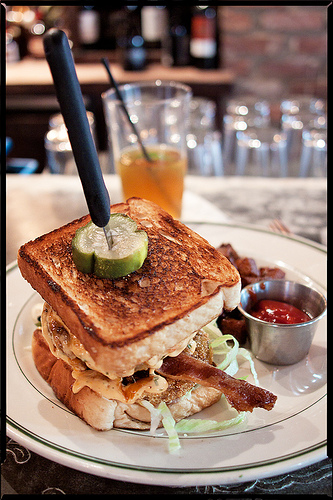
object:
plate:
[6, 217, 327, 487]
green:
[92, 255, 127, 280]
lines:
[7, 217, 330, 485]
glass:
[101, 80, 193, 223]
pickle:
[71, 213, 149, 280]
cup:
[236, 279, 328, 368]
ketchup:
[250, 295, 310, 324]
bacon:
[154, 352, 278, 412]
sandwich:
[17, 196, 279, 452]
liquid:
[115, 145, 187, 222]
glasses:
[45, 92, 327, 177]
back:
[0, 1, 327, 179]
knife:
[42, 28, 115, 254]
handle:
[42, 28, 112, 228]